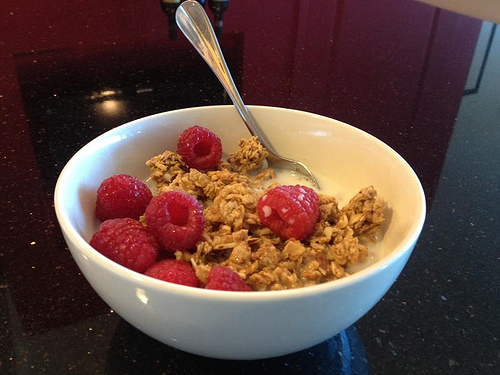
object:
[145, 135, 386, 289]
granola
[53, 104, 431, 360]
bowl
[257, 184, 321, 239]
raspberry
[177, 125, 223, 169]
raspberry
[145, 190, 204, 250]
raspberry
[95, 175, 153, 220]
raspberry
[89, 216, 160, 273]
raspberry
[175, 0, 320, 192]
spoon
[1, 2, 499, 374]
counter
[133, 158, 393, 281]
milk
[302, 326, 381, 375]
reflection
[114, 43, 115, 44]
specks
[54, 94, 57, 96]
specks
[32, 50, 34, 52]
specks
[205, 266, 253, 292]
raspberry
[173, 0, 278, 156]
handle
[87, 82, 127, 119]
reflection